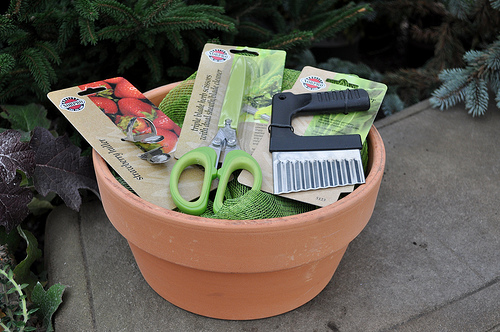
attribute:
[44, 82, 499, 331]
bench — gray, concrete, grey, cement, asphalt, large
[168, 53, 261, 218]
shears — new, green, large, light green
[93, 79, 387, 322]
planter — terracotta, red, clay, terra cotta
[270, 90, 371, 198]
tool — black, silver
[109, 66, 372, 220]
mesh — green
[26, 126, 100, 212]
plant — purple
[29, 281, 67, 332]
plant — green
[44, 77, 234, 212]
tool — new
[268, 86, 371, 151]
handle — black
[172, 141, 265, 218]
handle — green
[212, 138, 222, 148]
screw — silver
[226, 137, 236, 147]
screw — silver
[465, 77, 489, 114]
pine branch — blue